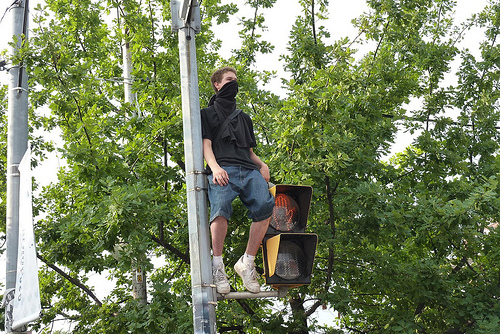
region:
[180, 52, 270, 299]
man is standing on pole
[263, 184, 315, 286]
crosswalk light is red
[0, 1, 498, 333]
green tree in background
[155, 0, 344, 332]
crosswalk light attached to pole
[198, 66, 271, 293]
man is wearing black shirt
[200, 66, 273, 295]
man is wearing blue shorts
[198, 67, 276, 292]
man is wearing white shoes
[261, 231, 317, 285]
light is not illuminated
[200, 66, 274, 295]
man is wearing white socks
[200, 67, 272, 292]
man is wearing black mask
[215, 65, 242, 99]
a man's face partially obscured by a black cloth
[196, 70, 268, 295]
a man standing on a light pole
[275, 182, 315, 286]
a set of crossing lights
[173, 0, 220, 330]
a large pole for traffic lights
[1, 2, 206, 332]
three traffic poles next to a clump of trees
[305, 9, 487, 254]
a large section of green trees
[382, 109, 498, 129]
a black power line extending through tree branches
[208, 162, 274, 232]
blue denim shorts on a man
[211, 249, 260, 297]
white sneakers and socks on a man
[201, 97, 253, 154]
black shirt on a man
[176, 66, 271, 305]
a boy has climbed up a steel pole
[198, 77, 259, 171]
the boy has his lower half of his face covered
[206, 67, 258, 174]
the boy has a black shirt on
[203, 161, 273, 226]
the bou is wearing blue jean cut offs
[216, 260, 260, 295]
the person is wearing white tennis shoes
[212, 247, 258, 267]
white socks are inside the sneakers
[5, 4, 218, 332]
three steel poles are near the trees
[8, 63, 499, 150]
wires are going through the trees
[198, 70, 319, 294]
the boy is sitting on the arm that holds the light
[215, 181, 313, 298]
the pedestrian red light indicates stop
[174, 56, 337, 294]
a man in black shirt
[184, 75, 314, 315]
a man standing on a light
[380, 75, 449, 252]
trees in the back ground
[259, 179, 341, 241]
a stop sign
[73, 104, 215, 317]
trees that are there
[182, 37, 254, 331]
a light pole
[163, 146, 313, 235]
jean shorts he is earing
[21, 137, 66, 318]
a advertisement hanging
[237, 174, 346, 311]
two lights held in a yellow holder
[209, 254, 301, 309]
white shoes of the boy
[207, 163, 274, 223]
a pair of blue jean shorts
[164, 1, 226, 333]
a tall traffic pole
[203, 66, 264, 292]
a man standing on traffic pole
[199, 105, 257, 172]
a black tee shirt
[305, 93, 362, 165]
green leaves of tree in background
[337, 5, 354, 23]
white sky above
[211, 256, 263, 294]
white gym shoes on mans feet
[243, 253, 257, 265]
white sock on mans foot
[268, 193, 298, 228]
an orange glowing hand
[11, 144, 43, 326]
a white flag on pole